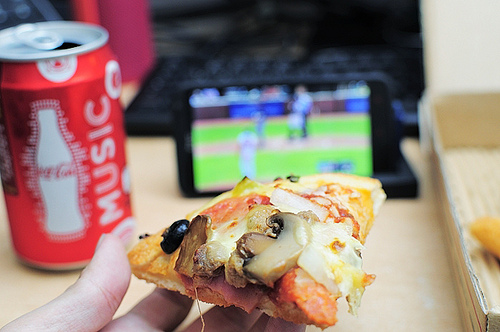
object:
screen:
[185, 82, 376, 193]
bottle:
[27, 97, 93, 240]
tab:
[16, 31, 64, 52]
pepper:
[232, 175, 262, 197]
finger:
[0, 230, 131, 330]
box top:
[409, 86, 498, 329]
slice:
[124, 171, 389, 326]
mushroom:
[237, 213, 314, 286]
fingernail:
[93, 231, 107, 255]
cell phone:
[175, 72, 399, 198]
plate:
[248, 175, 336, 231]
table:
[372, 264, 431, 332]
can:
[2, 18, 144, 275]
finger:
[100, 286, 190, 330]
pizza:
[132, 169, 388, 330]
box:
[425, 86, 499, 327]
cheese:
[313, 180, 373, 232]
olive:
[160, 219, 190, 254]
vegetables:
[245, 207, 366, 301]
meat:
[193, 223, 264, 311]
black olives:
[160, 219, 191, 255]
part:
[233, 132, 261, 152]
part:
[243, 210, 276, 259]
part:
[464, 141, 476, 169]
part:
[55, 294, 90, 318]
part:
[56, 304, 87, 325]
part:
[273, 249, 292, 274]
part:
[415, 279, 445, 326]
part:
[262, 120, 311, 153]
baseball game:
[176, 77, 380, 190]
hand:
[0, 221, 319, 331]